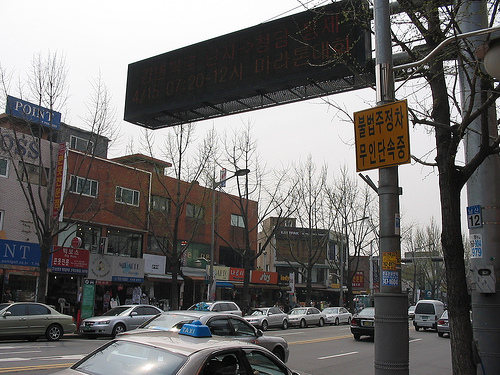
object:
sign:
[353, 98, 411, 173]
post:
[372, 0, 410, 374]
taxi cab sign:
[177, 320, 211, 339]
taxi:
[54, 320, 302, 374]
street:
[1, 318, 455, 374]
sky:
[0, 0, 499, 268]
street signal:
[122, 0, 378, 118]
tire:
[45, 324, 63, 343]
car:
[0, 301, 78, 343]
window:
[72, 339, 187, 374]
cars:
[287, 307, 327, 329]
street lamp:
[206, 168, 250, 303]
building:
[50, 149, 259, 327]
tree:
[269, 153, 344, 306]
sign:
[52, 246, 90, 269]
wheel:
[259, 320, 268, 332]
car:
[244, 307, 289, 331]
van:
[413, 298, 447, 331]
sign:
[5, 95, 62, 132]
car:
[350, 305, 376, 342]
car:
[110, 310, 288, 367]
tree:
[285, 0, 500, 374]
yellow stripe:
[287, 335, 355, 345]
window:
[114, 185, 141, 208]